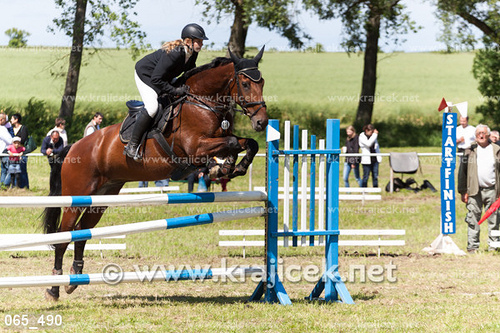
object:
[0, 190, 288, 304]
hurdle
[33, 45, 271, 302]
horse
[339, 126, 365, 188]
woman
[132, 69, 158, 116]
riding pants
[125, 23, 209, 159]
woman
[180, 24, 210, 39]
helmet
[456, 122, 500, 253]
man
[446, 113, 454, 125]
letter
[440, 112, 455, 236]
sign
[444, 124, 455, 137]
letter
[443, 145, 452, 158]
letter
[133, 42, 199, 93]
jacket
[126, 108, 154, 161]
boots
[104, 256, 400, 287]
watermark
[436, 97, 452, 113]
flag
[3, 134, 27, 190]
kid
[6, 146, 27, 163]
shirt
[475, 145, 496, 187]
shirt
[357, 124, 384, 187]
woman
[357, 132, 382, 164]
coat